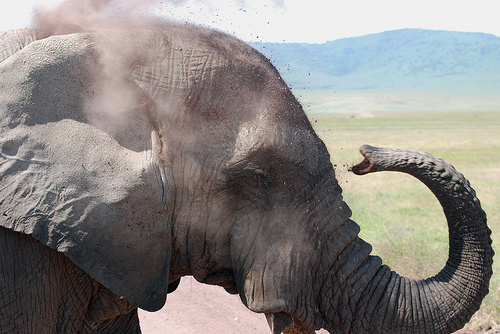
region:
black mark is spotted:
[484, 319, 491, 329]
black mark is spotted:
[487, 320, 492, 330]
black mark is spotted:
[482, 320, 487, 328]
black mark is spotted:
[483, 316, 493, 332]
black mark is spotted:
[482, 313, 487, 331]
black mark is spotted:
[477, 320, 487, 332]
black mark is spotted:
[487, 325, 499, 332]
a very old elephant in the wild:
[5, 29, 456, 329]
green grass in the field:
[396, 111, 473, 148]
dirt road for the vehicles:
[171, 290, 243, 331]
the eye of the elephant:
[224, 155, 298, 197]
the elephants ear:
[5, 48, 179, 312]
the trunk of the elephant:
[339, 137, 489, 332]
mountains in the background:
[312, 21, 480, 95]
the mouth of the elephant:
[255, 301, 323, 332]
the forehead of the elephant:
[139, 10, 301, 115]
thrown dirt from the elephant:
[260, 28, 388, 107]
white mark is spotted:
[227, 313, 235, 322]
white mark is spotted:
[233, 313, 251, 328]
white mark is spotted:
[236, 308, 247, 333]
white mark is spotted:
[228, 308, 241, 331]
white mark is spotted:
[237, 311, 240, 326]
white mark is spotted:
[229, 312, 243, 323]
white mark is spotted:
[231, 308, 237, 330]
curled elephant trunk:
[337, 130, 498, 332]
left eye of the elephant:
[225, 152, 291, 212]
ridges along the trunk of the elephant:
[332, 183, 409, 293]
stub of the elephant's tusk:
[257, 304, 295, 332]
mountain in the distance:
[318, 22, 498, 107]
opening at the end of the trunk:
[343, 141, 377, 178]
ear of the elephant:
[0, 27, 177, 312]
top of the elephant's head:
[67, 15, 307, 85]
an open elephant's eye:
[216, 135, 303, 214]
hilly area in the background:
[235, 20, 495, 100]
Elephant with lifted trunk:
[15, 12, 479, 314]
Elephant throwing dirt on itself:
[309, 91, 482, 313]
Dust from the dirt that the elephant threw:
[15, 6, 212, 142]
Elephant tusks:
[259, 291, 287, 328]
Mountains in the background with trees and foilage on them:
[246, 21, 495, 108]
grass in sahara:
[352, 119, 498, 228]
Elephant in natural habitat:
[6, 15, 424, 314]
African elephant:
[3, 38, 323, 251]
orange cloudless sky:
[222, 12, 492, 84]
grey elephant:
[46, 72, 391, 308]